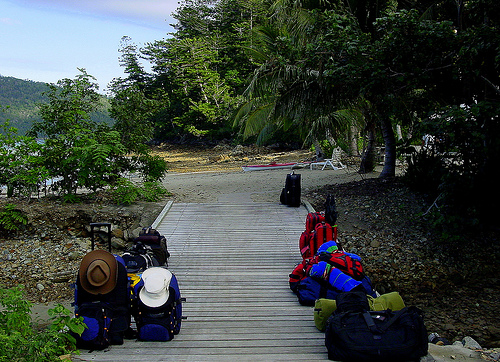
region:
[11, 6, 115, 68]
white and gray clouds in sky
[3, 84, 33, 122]
green plant covered hill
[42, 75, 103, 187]
brown tree with green leaves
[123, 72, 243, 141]
brown tree with green leaves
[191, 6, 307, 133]
brown tree with green leaves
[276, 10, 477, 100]
brown tree with green leaves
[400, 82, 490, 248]
brown tree with green leaves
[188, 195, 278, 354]
gray wooden sidewalk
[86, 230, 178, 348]
blue and black baggage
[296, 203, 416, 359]
blue black and red luggage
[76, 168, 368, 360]
Luggage of the travelors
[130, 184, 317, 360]
A wooden walkway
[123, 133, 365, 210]
A small sandy beach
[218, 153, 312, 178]
Some sort of a canoe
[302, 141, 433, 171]
Lounging area of the beach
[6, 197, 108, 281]
Rocky area of the beach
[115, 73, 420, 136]
Tree line of the beach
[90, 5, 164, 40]
Clouds off in the distance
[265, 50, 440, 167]
are these palm trees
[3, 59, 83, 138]
A distant hillside/mountian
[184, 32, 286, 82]
green leaves on trees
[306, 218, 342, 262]
red and black backpack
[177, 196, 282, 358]
slats of wooden foot bridge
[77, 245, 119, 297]
brown cowboy hat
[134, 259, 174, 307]
white cowboy hat hooked onto backpack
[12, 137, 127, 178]
water behind the trees in the distance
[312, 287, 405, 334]
green sleeping bag rolled up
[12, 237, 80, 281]
rocks on side of bridge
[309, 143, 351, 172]
chaise lounge in the shade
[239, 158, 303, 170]
red and white boat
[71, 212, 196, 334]
Luggage left on dock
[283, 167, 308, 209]
Black bag towards end of dock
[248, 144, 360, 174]
Empty kayak and beach chair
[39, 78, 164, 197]
Tree near the river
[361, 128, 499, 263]
Shade cast by a neighboring tree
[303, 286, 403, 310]
Small green roll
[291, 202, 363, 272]
Red bag aligned in a row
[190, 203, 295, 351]
Planks of dock beneath bags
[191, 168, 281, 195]
Sand of the shore is brown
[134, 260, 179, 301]
White hat is large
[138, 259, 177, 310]
The hat is white.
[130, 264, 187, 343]
The backpack is blue.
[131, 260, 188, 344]
The hat is on the backpack.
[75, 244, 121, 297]
The hat is brown.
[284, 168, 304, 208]
The luggage is black.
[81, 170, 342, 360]
The walkway is wooden.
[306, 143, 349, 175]
The lawn chair is white.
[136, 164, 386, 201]
The ground is sandy.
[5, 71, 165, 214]
The trees are leafy.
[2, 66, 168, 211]
The trees are green.